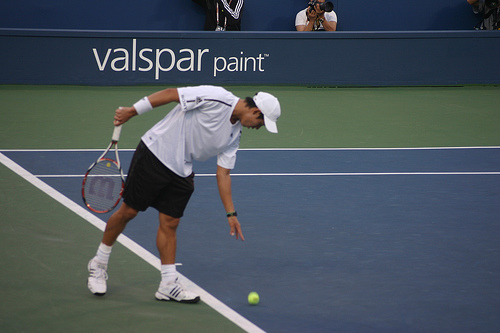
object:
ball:
[247, 290, 261, 305]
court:
[0, 0, 499, 332]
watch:
[225, 211, 237, 218]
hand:
[226, 212, 246, 241]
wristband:
[133, 96, 155, 116]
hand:
[113, 105, 136, 126]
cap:
[251, 91, 282, 134]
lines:
[0, 145, 499, 152]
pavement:
[0, 86, 499, 332]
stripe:
[186, 98, 233, 109]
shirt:
[140, 84, 243, 178]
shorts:
[121, 138, 195, 218]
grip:
[111, 106, 125, 141]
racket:
[81, 105, 126, 213]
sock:
[93, 241, 114, 269]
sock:
[160, 261, 183, 285]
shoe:
[87, 255, 109, 296]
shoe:
[153, 277, 200, 304]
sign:
[92, 37, 272, 81]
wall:
[0, 31, 499, 86]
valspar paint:
[268, 36, 381, 75]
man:
[295, 0, 337, 31]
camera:
[307, 0, 335, 14]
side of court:
[0, 0, 499, 28]